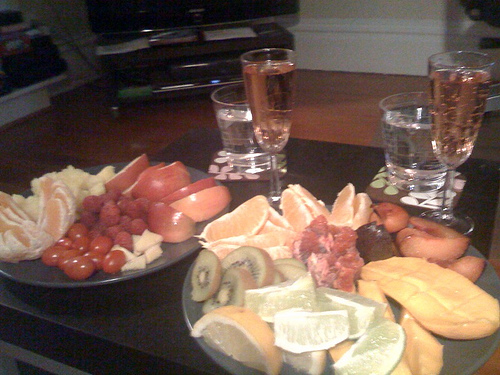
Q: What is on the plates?
A: Food.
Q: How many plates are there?
A: Two.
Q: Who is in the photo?
A: Nobody.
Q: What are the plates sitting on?
A: The table.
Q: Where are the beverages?
A: In the glasses.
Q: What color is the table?
A: Black.